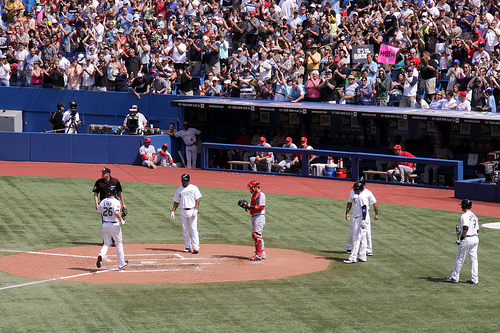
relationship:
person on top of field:
[169, 173, 200, 256] [4, 163, 498, 332]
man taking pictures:
[65, 102, 80, 133] [69, 111, 78, 119]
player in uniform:
[239, 181, 268, 262] [177, 188, 200, 251]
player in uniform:
[248, 136, 276, 175] [177, 188, 200, 251]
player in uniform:
[344, 182, 370, 265] [347, 198, 365, 265]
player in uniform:
[448, 200, 482, 291] [452, 214, 481, 282]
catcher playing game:
[239, 181, 268, 262] [4, 163, 498, 332]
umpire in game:
[239, 181, 268, 262] [4, 163, 498, 332]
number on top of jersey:
[103, 202, 116, 221] [100, 199, 121, 223]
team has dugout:
[130, 122, 449, 177] [175, 103, 499, 177]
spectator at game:
[3, 3, 499, 109] [4, 163, 498, 332]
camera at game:
[128, 110, 137, 129] [4, 163, 498, 332]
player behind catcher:
[344, 182, 370, 265] [239, 181, 268, 262]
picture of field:
[69, 111, 78, 119] [4, 163, 498, 332]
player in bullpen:
[248, 136, 276, 175] [175, 103, 499, 177]